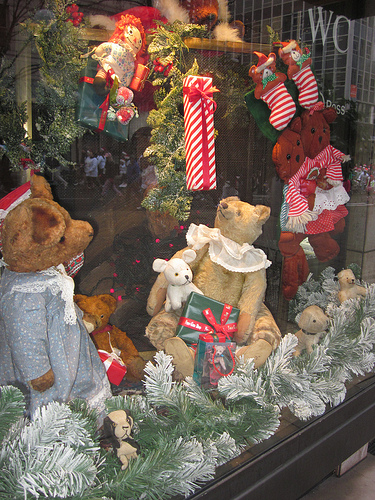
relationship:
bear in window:
[5, 159, 126, 431] [1, 2, 363, 498]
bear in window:
[246, 52, 298, 127] [1, 2, 363, 498]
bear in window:
[274, 39, 315, 106] [1, 2, 363, 498]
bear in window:
[273, 118, 340, 295] [1, 2, 363, 498]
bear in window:
[292, 107, 349, 244] [1, 2, 363, 498]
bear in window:
[335, 268, 367, 306] [1, 2, 363, 498]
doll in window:
[83, 18, 152, 111] [5, 6, 367, 437]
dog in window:
[151, 247, 202, 308] [1, 2, 363, 498]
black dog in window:
[103, 408, 141, 470] [1, 2, 363, 498]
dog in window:
[292, 304, 330, 359] [1, 2, 363, 498]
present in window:
[78, 63, 129, 143] [17, 35, 160, 203]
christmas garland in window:
[181, 75, 217, 190] [11, 31, 365, 458]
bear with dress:
[0, 196, 112, 434] [0, 262, 117, 443]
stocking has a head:
[246, 50, 296, 132] [247, 53, 276, 80]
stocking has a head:
[289, 63, 321, 110] [272, 35, 304, 63]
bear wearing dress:
[0, 196, 112, 434] [0, 262, 114, 435]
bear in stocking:
[248, 50, 296, 132] [252, 73, 295, 128]